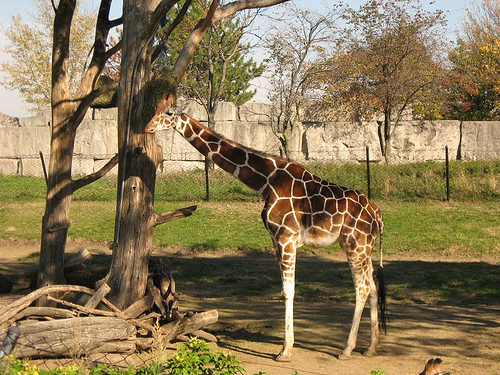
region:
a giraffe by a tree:
[119, 83, 435, 363]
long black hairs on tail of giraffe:
[373, 261, 396, 333]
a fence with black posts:
[19, 131, 492, 207]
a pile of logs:
[12, 253, 231, 366]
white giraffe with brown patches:
[147, 94, 420, 364]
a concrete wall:
[2, 93, 499, 187]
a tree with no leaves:
[151, 5, 271, 237]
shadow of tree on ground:
[18, 202, 497, 359]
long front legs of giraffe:
[257, 229, 310, 372]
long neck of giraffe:
[172, 115, 273, 186]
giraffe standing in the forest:
[147, 94, 419, 360]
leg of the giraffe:
[261, 231, 322, 363]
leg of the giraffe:
[145, 100, 228, 175]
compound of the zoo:
[283, 113, 495, 182]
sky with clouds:
[323, 10, 482, 51]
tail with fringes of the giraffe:
[378, 230, 397, 334]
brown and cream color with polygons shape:
[235, 150, 364, 242]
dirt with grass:
[416, 200, 481, 357]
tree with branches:
[334, 28, 428, 177]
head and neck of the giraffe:
[141, 87, 263, 187]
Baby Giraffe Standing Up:
[140, 89, 386, 364]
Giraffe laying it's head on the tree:
[139, 90, 192, 141]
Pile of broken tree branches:
[0, 270, 220, 358]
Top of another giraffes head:
[409, 358, 453, 373]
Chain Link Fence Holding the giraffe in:
[3, 152, 498, 202]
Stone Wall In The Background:
[1, 120, 495, 175]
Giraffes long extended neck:
[175, 108, 267, 197]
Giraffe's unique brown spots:
[260, 164, 380, 248]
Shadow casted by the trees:
[22, 241, 498, 352]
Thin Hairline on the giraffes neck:
[180, 108, 285, 165]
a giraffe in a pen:
[134, 78, 401, 365]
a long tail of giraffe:
[374, 208, 396, 336]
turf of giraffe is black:
[373, 263, 394, 336]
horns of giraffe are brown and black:
[151, 83, 180, 111]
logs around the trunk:
[9, 219, 226, 368]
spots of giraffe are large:
[182, 120, 312, 222]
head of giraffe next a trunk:
[105, 72, 203, 167]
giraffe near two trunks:
[30, 2, 400, 328]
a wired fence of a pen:
[290, 138, 485, 203]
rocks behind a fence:
[254, 100, 494, 155]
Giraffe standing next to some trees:
[142, 90, 389, 360]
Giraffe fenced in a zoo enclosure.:
[142, 89, 395, 364]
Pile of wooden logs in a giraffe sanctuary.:
[0, 275, 227, 362]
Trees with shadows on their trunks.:
[40, 35, 143, 310]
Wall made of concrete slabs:
[268, 92, 495, 161]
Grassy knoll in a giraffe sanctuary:
[383, 197, 494, 253]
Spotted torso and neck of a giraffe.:
[142, 92, 388, 249]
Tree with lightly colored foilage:
[302, 62, 474, 197]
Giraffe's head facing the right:
[140, 92, 190, 138]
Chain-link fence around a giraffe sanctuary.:
[355, 143, 495, 200]